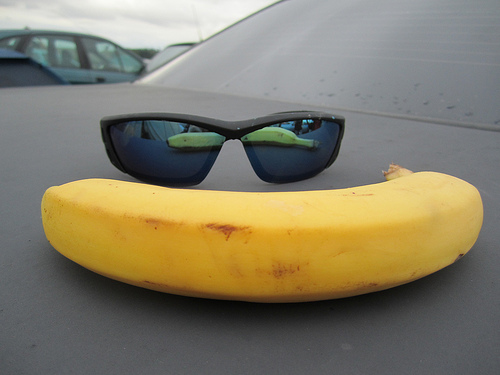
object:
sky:
[124, 14, 174, 34]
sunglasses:
[97, 108, 347, 189]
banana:
[40, 163, 484, 303]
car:
[1, 1, 499, 375]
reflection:
[166, 128, 319, 154]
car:
[1, 27, 149, 86]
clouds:
[1, 0, 280, 52]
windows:
[0, 26, 144, 77]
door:
[80, 34, 145, 88]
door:
[19, 32, 93, 86]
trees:
[50, 47, 164, 61]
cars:
[0, 28, 207, 89]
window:
[129, 0, 499, 136]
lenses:
[101, 111, 346, 187]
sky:
[0, 1, 275, 52]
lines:
[207, 0, 496, 66]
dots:
[130, 75, 499, 129]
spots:
[140, 215, 255, 238]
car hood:
[2, 79, 499, 374]